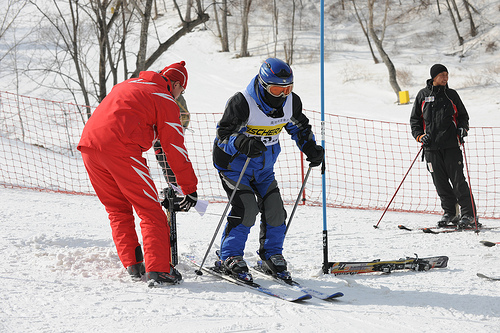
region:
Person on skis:
[194, 56, 342, 304]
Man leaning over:
[76, 56, 201, 289]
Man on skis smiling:
[373, 63, 497, 235]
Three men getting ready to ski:
[76, 57, 488, 302]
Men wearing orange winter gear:
[76, 59, 199, 290]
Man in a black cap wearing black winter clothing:
[407, 62, 478, 229]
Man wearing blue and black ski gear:
[210, 57, 323, 283]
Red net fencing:
[0, 89, 497, 219]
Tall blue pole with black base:
[315, 0, 335, 275]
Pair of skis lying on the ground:
[322, 254, 449, 274]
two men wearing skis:
[212, 60, 481, 307]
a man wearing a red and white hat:
[159, 55, 206, 106]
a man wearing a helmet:
[253, 53, 303, 108]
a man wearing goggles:
[268, 72, 306, 109]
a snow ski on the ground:
[325, 252, 456, 295]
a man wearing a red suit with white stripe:
[95, 64, 179, 325]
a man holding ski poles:
[186, 116, 327, 292]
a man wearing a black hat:
[420, 57, 460, 101]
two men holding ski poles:
[226, 72, 491, 280]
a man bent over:
[121, 59, 194, 273]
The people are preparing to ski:
[36, 20, 486, 311]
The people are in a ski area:
[16, 30, 496, 310]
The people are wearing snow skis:
[198, 20, 481, 315]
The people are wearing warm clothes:
[206, 30, 496, 303]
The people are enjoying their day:
[200, 33, 490, 309]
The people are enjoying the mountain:
[203, 32, 494, 299]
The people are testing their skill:
[201, 20, 496, 318]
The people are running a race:
[210, 35, 490, 315]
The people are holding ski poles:
[203, 30, 494, 313]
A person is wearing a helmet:
[249, 48, 300, 113]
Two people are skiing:
[198, 61, 486, 306]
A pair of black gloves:
[231, 130, 326, 170]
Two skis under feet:
[189, 244, 346, 307]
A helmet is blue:
[256, 53, 295, 109]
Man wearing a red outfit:
[73, 56, 203, 289]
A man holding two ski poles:
[369, 62, 486, 237]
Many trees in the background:
[1, 1, 496, 160]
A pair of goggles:
[255, 70, 296, 99]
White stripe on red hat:
[157, 56, 191, 91]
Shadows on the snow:
[41, 231, 499, 320]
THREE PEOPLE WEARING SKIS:
[53, 58, 477, 308]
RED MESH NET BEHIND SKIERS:
[13, 81, 497, 235]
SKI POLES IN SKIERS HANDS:
[194, 137, 326, 294]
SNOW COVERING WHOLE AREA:
[11, 38, 491, 318]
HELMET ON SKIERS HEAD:
[222, 33, 319, 122]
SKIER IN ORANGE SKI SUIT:
[58, 44, 203, 297]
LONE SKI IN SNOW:
[321, 245, 467, 279]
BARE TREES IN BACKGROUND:
[7, 2, 485, 132]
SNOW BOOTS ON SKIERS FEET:
[194, 223, 310, 296]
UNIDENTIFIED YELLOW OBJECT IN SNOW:
[379, 78, 423, 114]